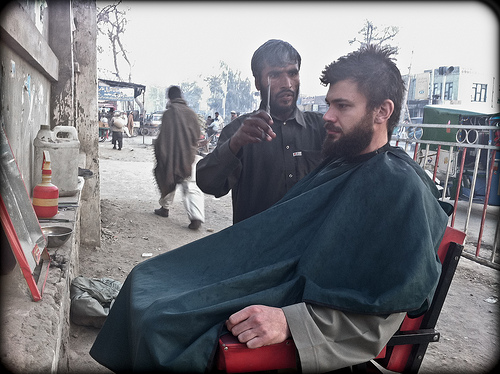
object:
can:
[31, 147, 60, 218]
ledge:
[1, 232, 71, 371]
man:
[153, 84, 201, 230]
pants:
[157, 153, 206, 222]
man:
[193, 39, 331, 256]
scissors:
[261, 75, 271, 139]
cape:
[88, 143, 449, 374]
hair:
[250, 38, 303, 100]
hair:
[318, 48, 405, 139]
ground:
[100, 134, 500, 374]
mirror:
[0, 123, 40, 272]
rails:
[430, 125, 500, 274]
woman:
[20, 74, 45, 124]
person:
[109, 110, 125, 150]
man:
[123, 47, 429, 374]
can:
[27, 123, 80, 196]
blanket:
[153, 96, 201, 198]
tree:
[350, 18, 399, 63]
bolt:
[433, 335, 440, 341]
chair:
[210, 226, 467, 374]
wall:
[23, 300, 66, 373]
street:
[96, 144, 500, 374]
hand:
[225, 303, 289, 349]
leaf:
[347, 38, 356, 46]